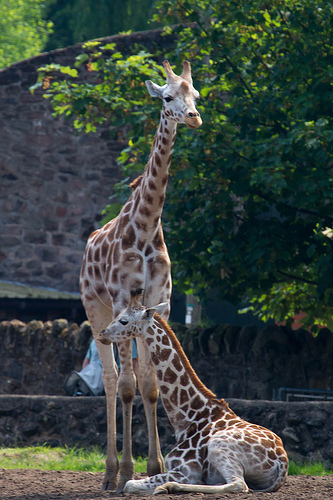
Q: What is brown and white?
A: The giraffe.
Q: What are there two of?
A: Giraffes.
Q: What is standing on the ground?
A: An animal.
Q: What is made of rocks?
A: A wall.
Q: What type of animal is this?
A: Giraffe.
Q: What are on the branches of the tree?
A: Leaves.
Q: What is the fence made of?
A: Stones.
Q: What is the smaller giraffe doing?
A: Lying down.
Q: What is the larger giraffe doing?
A: Standing up.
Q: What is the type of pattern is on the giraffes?
A: A brown and white pattern.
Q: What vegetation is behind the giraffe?
A: A tree.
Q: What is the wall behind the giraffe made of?
A: Stones.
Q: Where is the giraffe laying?
A: On the ground.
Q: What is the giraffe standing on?
A: The ground.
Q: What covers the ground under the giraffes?
A: Dirt.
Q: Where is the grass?
A: On the ground.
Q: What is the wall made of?
A: Stone.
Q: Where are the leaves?
A: On the tree.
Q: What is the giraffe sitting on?
A: The ground.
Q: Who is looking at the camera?
A: The giraffe.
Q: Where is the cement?
A: On the wall.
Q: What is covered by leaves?
A: Branches.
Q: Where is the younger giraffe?
A: Under the adult.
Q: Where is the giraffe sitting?
A: On the ground.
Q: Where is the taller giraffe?
A: Over the baby giraffe.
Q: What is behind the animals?
A: Stone wall.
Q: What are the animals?
A: Giraffes.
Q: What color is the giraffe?
A: Brown and white.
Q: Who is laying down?
A: Giraffe.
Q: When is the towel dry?
A: There is no towel.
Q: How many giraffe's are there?
A: Two.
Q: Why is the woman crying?
A: There is no woman.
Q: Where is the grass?
A: Behind giraffe.